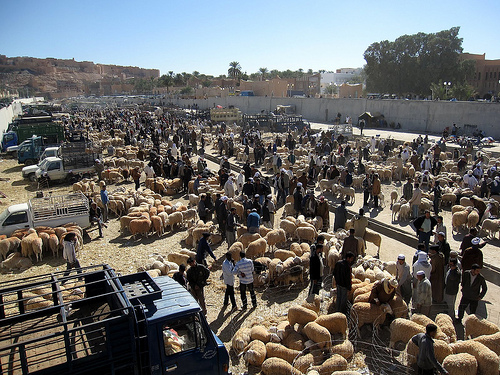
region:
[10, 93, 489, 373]
a sheep market in another country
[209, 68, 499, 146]
a gray stone wall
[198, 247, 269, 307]
a person hugging someone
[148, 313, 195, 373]
a pile of clothes in a truck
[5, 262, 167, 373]
a cage on a truck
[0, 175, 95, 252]
a white truck at market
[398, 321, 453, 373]
a person in gray shirt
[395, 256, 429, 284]
men wearing white hats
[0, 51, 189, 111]
a rock mountian in the background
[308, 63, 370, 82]
a white building in the back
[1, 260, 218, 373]
Black crated truck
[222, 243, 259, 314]
Two people talking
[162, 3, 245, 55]
Clear blue sunny day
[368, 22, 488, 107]
Green trees in background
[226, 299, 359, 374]
Herd of sheeps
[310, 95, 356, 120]
White barrier wall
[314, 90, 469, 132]
Tall white barrier wall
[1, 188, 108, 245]
White crated truck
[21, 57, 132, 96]
High hills over market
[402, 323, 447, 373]
Man standing in front of herd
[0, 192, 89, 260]
sheep near a white truck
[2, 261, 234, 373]
truck with a blue front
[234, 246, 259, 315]
man in a white striped shirt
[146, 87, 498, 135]
long cement fence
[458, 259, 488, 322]
man in a brown pullover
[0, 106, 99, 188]
trucks parked near a fence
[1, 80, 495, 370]
people at a sheep auction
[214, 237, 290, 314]
two men looking at sheep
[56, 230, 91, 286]
man wearing a white shirt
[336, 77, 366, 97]
small tan building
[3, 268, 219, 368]
a dark blue truck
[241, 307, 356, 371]
several sheep eating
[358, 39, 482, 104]
large leafy trees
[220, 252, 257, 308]
a loving couple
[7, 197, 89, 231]
a white truck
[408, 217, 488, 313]
several people in different positions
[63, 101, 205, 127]
a lot of people in the distance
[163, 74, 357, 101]
various houses in the distance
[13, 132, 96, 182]
several trucks ready to load the sheep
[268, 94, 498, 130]
a large concrete wall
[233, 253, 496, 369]
these are many sheep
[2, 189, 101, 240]
there is a white truck parked in this area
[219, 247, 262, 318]
these men seem to be looking at some of the sheep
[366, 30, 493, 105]
there are trees in the background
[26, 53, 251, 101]
there are several buildings in this area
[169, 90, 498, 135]
this is a large concrete fence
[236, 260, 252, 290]
this man is wearing a white striped shirt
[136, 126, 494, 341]
there is a large crowd of people here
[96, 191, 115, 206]
this man is wearing a blue shirt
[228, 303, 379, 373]
this is a small herd of sheep